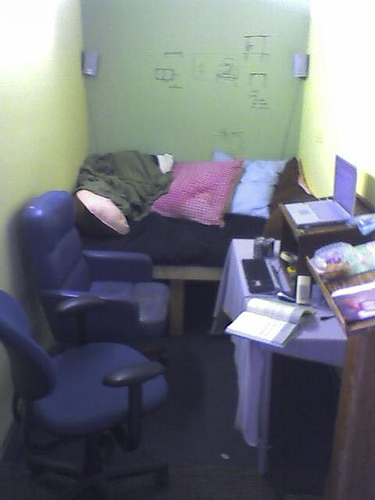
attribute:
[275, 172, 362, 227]
computer — laptop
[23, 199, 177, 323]
chairs — blue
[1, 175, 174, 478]
chairs — BLACK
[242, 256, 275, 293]
keyboard — black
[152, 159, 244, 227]
pillow — pink